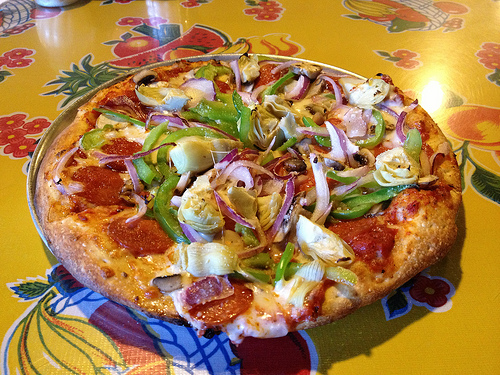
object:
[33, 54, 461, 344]
cheese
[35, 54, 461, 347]
peppers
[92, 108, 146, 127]
pepper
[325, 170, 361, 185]
pepper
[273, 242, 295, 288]
pepper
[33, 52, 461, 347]
pizza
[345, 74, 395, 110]
mushroom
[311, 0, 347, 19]
table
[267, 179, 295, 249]
onions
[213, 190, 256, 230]
onions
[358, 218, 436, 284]
crust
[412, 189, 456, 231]
crust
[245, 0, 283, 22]
flower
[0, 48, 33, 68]
flower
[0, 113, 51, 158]
flower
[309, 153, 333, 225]
onions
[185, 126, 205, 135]
peppers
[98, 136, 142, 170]
pepperoni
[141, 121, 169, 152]
green pepper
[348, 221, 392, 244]
sauce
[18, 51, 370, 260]
pan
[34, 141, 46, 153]
silver plate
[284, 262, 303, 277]
pepper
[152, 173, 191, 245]
artichoke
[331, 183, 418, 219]
artichoke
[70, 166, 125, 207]
pepperoni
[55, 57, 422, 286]
toppings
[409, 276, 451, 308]
flower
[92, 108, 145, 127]
green pepper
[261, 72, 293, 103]
green pepper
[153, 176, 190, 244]
green pepper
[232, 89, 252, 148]
green pepper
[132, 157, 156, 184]
green pepper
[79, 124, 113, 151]
green pepper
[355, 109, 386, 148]
green pepper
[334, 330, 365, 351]
shadow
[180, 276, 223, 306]
slice pepperoni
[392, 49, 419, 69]
flower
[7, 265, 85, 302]
flower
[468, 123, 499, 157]
table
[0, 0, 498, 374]
yellow tablecloth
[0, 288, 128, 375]
fruit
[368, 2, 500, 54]
colorful tablecloth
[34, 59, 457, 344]
pizza pie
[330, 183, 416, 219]
pepper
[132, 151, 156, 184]
pepper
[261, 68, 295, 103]
pepper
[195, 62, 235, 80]
pepper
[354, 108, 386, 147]
pepper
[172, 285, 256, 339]
cheese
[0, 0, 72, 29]
table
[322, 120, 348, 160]
red onions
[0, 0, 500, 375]
tablecloth